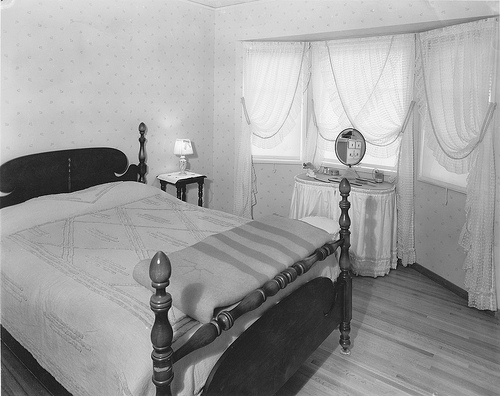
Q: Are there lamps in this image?
A: Yes, there is a lamp.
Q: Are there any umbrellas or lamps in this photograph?
A: Yes, there is a lamp.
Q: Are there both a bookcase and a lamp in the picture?
A: No, there is a lamp but no bookcases.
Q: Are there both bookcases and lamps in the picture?
A: No, there is a lamp but no bookcases.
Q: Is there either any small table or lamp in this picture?
A: Yes, there is a small lamp.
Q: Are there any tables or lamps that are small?
A: Yes, the lamp is small.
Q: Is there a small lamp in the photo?
A: Yes, there is a small lamp.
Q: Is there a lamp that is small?
A: Yes, there is a lamp that is small.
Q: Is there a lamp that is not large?
A: Yes, there is a small lamp.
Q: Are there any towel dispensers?
A: No, there are no towel dispensers.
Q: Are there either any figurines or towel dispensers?
A: No, there are no towel dispensers or figurines.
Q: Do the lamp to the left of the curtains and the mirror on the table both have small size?
A: Yes, both the lamp and the mirror are small.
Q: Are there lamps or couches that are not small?
A: No, there is a lamp but it is small.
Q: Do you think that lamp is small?
A: Yes, the lamp is small.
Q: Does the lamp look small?
A: Yes, the lamp is small.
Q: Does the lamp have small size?
A: Yes, the lamp is small.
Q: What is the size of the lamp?
A: The lamp is small.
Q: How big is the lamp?
A: The lamp is small.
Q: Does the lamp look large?
A: No, the lamp is small.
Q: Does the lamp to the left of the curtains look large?
A: No, the lamp is small.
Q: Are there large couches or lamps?
A: No, there is a lamp but it is small.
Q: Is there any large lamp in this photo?
A: No, there is a lamp but it is small.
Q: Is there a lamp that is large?
A: No, there is a lamp but it is small.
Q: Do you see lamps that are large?
A: No, there is a lamp but it is small.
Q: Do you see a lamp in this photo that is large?
A: No, there is a lamp but it is small.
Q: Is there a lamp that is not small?
A: No, there is a lamp but it is small.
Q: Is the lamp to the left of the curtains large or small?
A: The lamp is small.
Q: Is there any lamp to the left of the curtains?
A: Yes, there is a lamp to the left of the curtains.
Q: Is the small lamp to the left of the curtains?
A: Yes, the lamp is to the left of the curtains.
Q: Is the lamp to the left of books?
A: No, the lamp is to the left of the curtains.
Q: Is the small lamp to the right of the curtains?
A: No, the lamp is to the left of the curtains.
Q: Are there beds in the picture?
A: Yes, there is a bed.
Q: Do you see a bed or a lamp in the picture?
A: Yes, there is a bed.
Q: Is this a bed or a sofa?
A: This is a bed.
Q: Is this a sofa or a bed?
A: This is a bed.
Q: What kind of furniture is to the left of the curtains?
A: The piece of furniture is a bed.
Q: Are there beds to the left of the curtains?
A: Yes, there is a bed to the left of the curtains.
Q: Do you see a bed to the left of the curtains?
A: Yes, there is a bed to the left of the curtains.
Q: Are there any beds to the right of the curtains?
A: No, the bed is to the left of the curtains.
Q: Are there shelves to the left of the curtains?
A: No, there is a bed to the left of the curtains.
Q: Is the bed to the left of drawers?
A: No, the bed is to the left of the curtains.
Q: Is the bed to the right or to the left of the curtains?
A: The bed is to the left of the curtains.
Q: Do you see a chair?
A: No, there are no chairs.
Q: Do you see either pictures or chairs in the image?
A: No, there are no chairs or pictures.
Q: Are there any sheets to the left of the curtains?
A: Yes, there is a sheet to the left of the curtains.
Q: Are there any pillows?
A: Yes, there is a pillow.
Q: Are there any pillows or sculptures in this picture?
A: Yes, there is a pillow.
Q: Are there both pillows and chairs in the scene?
A: No, there is a pillow but no chairs.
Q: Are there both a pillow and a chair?
A: No, there is a pillow but no chairs.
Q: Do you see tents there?
A: No, there are no tents.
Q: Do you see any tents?
A: No, there are no tents.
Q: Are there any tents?
A: No, there are no tents.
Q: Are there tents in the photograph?
A: No, there are no tents.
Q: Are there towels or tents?
A: No, there are no tents or towels.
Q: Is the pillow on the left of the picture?
A: Yes, the pillow is on the left of the image.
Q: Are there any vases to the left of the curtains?
A: No, there is a pillow to the left of the curtains.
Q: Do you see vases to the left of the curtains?
A: No, there is a pillow to the left of the curtains.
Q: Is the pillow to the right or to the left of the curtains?
A: The pillow is to the left of the curtains.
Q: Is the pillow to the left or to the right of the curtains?
A: The pillow is to the left of the curtains.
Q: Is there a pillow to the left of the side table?
A: Yes, there is a pillow to the left of the side table.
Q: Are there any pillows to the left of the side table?
A: Yes, there is a pillow to the left of the side table.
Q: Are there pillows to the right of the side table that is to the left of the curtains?
A: No, the pillow is to the left of the side table.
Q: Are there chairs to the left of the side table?
A: No, there is a pillow to the left of the side table.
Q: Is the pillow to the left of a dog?
A: No, the pillow is to the left of the side table.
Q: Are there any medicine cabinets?
A: No, there are no medicine cabinets.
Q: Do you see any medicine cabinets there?
A: No, there are no medicine cabinets.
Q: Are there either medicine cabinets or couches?
A: No, there are no medicine cabinets or couches.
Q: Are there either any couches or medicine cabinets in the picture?
A: No, there are no medicine cabinets or couches.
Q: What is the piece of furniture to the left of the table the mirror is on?
A: The piece of furniture is a side table.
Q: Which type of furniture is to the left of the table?
A: The piece of furniture is a side table.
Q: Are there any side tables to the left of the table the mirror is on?
A: Yes, there is a side table to the left of the table.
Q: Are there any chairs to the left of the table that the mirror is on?
A: No, there is a side table to the left of the table.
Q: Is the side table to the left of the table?
A: Yes, the side table is to the left of the table.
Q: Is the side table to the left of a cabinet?
A: No, the side table is to the left of the table.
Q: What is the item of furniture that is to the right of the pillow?
A: The piece of furniture is a side table.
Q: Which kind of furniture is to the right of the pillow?
A: The piece of furniture is a side table.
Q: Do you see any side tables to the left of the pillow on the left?
A: No, the side table is to the right of the pillow.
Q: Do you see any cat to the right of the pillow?
A: No, there is a side table to the right of the pillow.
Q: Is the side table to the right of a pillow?
A: Yes, the side table is to the right of a pillow.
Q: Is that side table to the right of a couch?
A: No, the side table is to the right of a pillow.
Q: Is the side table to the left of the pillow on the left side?
A: No, the side table is to the right of the pillow.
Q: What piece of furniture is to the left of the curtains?
A: The piece of furniture is a side table.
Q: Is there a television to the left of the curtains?
A: No, there is a side table to the left of the curtains.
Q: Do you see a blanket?
A: Yes, there is a blanket.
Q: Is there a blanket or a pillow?
A: Yes, there is a blanket.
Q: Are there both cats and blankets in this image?
A: No, there is a blanket but no cats.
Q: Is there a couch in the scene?
A: No, there are no couches.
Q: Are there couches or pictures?
A: No, there are no couches or pictures.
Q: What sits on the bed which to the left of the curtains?
A: The blanket sits on the bed.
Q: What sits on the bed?
A: The blanket sits on the bed.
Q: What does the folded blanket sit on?
A: The blanket sits on the bed.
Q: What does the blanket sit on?
A: The blanket sits on the bed.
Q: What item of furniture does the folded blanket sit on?
A: The blanket sits on the bed.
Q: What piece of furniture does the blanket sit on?
A: The blanket sits on the bed.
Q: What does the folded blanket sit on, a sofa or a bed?
A: The blanket sits on a bed.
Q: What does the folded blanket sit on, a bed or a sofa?
A: The blanket sits on a bed.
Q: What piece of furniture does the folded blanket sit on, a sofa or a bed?
A: The blanket sits on a bed.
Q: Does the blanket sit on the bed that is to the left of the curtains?
A: Yes, the blanket sits on the bed.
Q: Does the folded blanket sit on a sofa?
A: No, the blanket sits on the bed.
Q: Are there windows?
A: Yes, there is a window.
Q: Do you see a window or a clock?
A: Yes, there is a window.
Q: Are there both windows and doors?
A: No, there is a window but no doors.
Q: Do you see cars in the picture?
A: No, there are no cars.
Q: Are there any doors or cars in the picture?
A: No, there are no cars or doors.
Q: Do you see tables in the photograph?
A: Yes, there is a table.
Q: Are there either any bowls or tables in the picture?
A: Yes, there is a table.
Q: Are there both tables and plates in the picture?
A: No, there is a table but no plates.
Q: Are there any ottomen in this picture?
A: No, there are no ottomen.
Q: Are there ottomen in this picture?
A: No, there are no ottomen.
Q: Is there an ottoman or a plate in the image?
A: No, there are no ottomen or plates.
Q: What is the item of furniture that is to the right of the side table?
A: The piece of furniture is a table.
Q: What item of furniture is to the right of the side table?
A: The piece of furniture is a table.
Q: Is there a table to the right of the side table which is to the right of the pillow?
A: Yes, there is a table to the right of the side table.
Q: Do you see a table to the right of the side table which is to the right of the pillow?
A: Yes, there is a table to the right of the side table.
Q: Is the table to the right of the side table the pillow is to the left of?
A: Yes, the table is to the right of the side table.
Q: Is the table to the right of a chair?
A: No, the table is to the right of the side table.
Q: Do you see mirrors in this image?
A: Yes, there is a mirror.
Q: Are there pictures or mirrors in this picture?
A: Yes, there is a mirror.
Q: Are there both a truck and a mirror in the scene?
A: No, there is a mirror but no trucks.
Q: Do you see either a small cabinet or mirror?
A: Yes, there is a small mirror.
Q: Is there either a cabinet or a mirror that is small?
A: Yes, the mirror is small.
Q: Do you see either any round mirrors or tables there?
A: Yes, there is a round mirror.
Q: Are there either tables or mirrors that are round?
A: Yes, the mirror is round.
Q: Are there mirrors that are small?
A: Yes, there is a small mirror.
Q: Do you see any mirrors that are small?
A: Yes, there is a mirror that is small.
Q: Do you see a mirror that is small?
A: Yes, there is a mirror that is small.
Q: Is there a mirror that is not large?
A: Yes, there is a small mirror.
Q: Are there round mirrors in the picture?
A: Yes, there is a round mirror.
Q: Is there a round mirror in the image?
A: Yes, there is a round mirror.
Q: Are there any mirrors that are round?
A: Yes, there is a mirror that is round.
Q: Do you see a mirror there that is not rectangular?
A: Yes, there is a round mirror.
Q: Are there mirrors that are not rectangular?
A: Yes, there is a round mirror.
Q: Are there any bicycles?
A: No, there are no bicycles.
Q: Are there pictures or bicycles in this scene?
A: No, there are no bicycles or pictures.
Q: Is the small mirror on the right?
A: Yes, the mirror is on the right of the image.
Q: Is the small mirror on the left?
A: No, the mirror is on the right of the image.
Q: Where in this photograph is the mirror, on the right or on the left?
A: The mirror is on the right of the image.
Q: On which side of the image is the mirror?
A: The mirror is on the right of the image.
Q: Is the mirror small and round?
A: Yes, the mirror is small and round.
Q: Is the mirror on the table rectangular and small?
A: No, the mirror is small but round.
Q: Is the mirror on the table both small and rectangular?
A: No, the mirror is small but round.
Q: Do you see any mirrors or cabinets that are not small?
A: No, there is a mirror but it is small.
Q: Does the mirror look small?
A: Yes, the mirror is small.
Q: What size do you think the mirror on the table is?
A: The mirror is small.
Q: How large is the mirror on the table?
A: The mirror is small.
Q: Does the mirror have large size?
A: No, the mirror is small.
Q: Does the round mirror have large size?
A: No, the mirror is small.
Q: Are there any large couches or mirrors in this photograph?
A: No, there is a mirror but it is small.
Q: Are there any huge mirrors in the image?
A: No, there is a mirror but it is small.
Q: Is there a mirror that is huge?
A: No, there is a mirror but it is small.